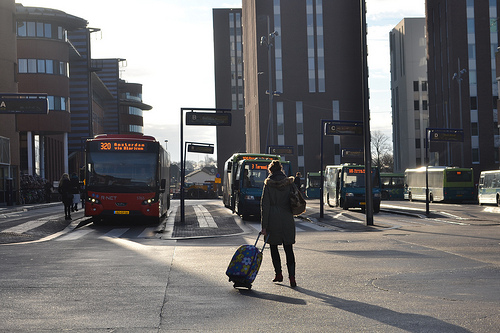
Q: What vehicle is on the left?
A: A bus.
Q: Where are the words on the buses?
A: The marquee.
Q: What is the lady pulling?
A: A rolling suitcase.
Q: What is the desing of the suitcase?
A: Flowers.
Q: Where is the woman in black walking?
A: On the sidewalk.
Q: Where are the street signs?
A: In the middle of the street.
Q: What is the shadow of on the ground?
A: Lady.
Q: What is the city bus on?
A: Road.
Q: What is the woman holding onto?
A: Luggage.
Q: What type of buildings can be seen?
A: Tall.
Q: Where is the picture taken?
A: Bus depot.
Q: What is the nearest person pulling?
A: Suitcase.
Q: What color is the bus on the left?
A: Red.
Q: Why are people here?
A: To catch a bus.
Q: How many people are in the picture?
A: Two.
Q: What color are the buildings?
A: Brown.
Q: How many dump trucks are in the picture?
A: None.